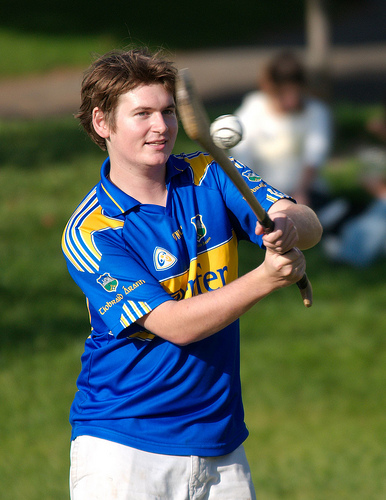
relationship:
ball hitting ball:
[209, 113, 243, 149] [198, 107, 251, 150]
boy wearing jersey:
[60, 44, 324, 500] [59, 151, 297, 455]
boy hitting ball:
[58, 50, 325, 443] [206, 112, 247, 150]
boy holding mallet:
[60, 44, 324, 500] [174, 94, 322, 304]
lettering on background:
[165, 264, 231, 303] [158, 232, 240, 305]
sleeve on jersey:
[68, 232, 169, 338] [61, 151, 297, 456]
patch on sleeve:
[94, 269, 119, 294] [68, 232, 169, 338]